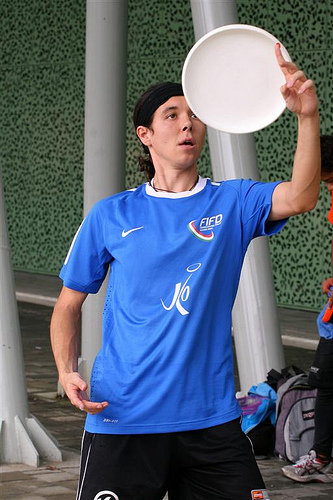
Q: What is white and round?
A: Frisbee.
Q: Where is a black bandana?
A: Around man's head.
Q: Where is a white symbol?
A: On blue shirt.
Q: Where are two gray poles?
A: Behind the guy.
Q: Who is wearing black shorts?
A: The guy.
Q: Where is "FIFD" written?
A: On blue shirt.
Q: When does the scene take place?
A: During daytime.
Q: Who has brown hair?
A: The young man.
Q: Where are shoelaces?
A: On a sneaker.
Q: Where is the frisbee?
A: In the man's hand.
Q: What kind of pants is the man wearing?
A: Shorts.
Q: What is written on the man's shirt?
A: FIFD.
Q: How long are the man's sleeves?
A: Short.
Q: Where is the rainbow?
A: Right shoulder.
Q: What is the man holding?
A: Frisbee.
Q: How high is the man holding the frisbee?
A: Head level.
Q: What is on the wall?
A: Black dots.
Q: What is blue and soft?
A: Shirt.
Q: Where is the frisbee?
A: In the boy's hand.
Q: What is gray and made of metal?
A: Pole.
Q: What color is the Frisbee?
A: White.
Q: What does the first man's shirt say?
A: FIFD.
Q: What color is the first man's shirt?
A: Blue.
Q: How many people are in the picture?
A: 2.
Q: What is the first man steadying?
A: A Frisbee.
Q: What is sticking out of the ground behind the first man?
A: Poles.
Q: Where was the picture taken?
A: By the metal pillars.